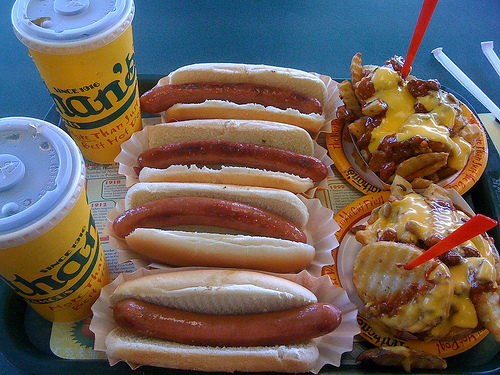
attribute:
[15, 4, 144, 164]
cup — yellow, plastic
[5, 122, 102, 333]
cup — yellow, plastic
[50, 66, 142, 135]
writing — green, red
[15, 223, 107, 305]
writing — green, red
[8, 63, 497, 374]
tray — blue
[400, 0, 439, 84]
fork — plastic, red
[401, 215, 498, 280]
fork — plastic, red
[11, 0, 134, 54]
lid — plastic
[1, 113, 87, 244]
lid — plastic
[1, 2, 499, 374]
table — blue